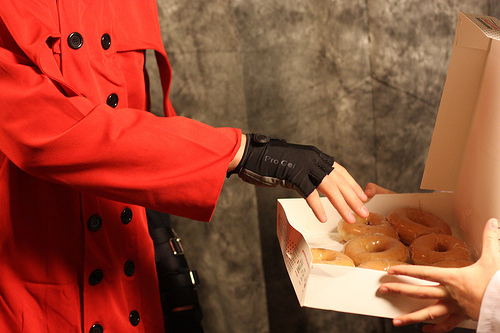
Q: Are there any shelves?
A: No, there are no shelves.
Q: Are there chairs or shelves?
A: No, there are no shelves or chairs.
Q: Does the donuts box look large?
A: Yes, the box is large.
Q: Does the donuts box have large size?
A: Yes, the box is large.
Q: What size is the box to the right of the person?
A: The box is large.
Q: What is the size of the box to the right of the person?
A: The box is large.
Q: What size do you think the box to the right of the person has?
A: The box has large size.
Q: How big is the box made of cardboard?
A: The box is large.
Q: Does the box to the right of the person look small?
A: No, the box is large.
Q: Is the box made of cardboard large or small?
A: The box is large.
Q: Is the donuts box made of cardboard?
A: Yes, the box is made of cardboard.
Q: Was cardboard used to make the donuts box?
A: Yes, the box is made of cardboard.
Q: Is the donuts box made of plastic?
A: No, the box is made of cardboard.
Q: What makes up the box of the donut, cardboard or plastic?
A: The box is made of cardboard.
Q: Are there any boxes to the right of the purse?
A: Yes, there is a box to the right of the purse.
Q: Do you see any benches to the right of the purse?
A: No, there is a box to the right of the purse.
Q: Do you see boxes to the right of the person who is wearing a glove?
A: Yes, there is a box to the right of the person.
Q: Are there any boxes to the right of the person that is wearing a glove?
A: Yes, there is a box to the right of the person.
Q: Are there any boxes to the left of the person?
A: No, the box is to the right of the person.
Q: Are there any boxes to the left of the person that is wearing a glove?
A: No, the box is to the right of the person.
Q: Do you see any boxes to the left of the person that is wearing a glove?
A: No, the box is to the right of the person.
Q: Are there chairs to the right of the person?
A: No, there is a box to the right of the person.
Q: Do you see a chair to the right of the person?
A: No, there is a box to the right of the person.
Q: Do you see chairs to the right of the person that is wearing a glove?
A: No, there is a box to the right of the person.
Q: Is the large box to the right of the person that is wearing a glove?
A: Yes, the box is to the right of the person.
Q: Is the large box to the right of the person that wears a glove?
A: Yes, the box is to the right of the person.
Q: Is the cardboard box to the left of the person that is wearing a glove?
A: No, the box is to the right of the person.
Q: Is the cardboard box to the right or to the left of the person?
A: The box is to the right of the person.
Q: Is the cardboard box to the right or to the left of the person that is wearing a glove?
A: The box is to the right of the person.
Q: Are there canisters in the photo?
A: No, there are no canisters.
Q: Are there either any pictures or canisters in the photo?
A: No, there are no canisters or pictures.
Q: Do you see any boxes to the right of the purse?
A: Yes, there is a box to the right of the purse.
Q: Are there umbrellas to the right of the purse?
A: No, there is a box to the right of the purse.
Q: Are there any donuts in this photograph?
A: Yes, there is a donut.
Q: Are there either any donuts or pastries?
A: Yes, there is a donut.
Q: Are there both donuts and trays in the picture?
A: No, there is a donut but no trays.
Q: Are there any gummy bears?
A: No, there are no gummy bears.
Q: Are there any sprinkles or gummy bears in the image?
A: No, there are no gummy bears or sprinkles.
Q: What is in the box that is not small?
A: The doughnut is in the box.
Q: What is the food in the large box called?
A: The food is a donut.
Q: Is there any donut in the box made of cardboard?
A: Yes, there is a donut in the box.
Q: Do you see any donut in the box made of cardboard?
A: Yes, there is a donut in the box.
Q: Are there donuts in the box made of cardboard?
A: Yes, there is a donut in the box.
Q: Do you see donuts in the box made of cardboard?
A: Yes, there is a donut in the box.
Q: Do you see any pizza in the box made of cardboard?
A: No, there is a donut in the box.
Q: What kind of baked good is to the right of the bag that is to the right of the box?
A: The food is a donut.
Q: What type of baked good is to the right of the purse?
A: The food is a donut.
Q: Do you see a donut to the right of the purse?
A: Yes, there is a donut to the right of the purse.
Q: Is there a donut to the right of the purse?
A: Yes, there is a donut to the right of the purse.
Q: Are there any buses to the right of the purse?
A: No, there is a donut to the right of the purse.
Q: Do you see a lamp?
A: No, there are no lamps.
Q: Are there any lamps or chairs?
A: No, there are no lamps or chairs.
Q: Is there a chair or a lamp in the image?
A: No, there are no lamps or chairs.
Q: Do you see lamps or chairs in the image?
A: No, there are no lamps or chairs.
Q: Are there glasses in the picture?
A: No, there are no glasses.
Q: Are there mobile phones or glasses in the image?
A: No, there are no glasses or mobile phones.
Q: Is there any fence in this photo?
A: No, there are no fences.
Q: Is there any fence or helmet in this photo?
A: No, there are no fences or helmets.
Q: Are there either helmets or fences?
A: No, there are no fences or helmets.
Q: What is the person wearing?
A: The person is wearing a glove.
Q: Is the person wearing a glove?
A: Yes, the person is wearing a glove.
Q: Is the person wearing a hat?
A: No, the person is wearing a glove.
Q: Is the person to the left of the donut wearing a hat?
A: No, the person is wearing a glove.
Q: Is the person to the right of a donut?
A: No, the person is to the left of a donut.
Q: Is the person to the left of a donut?
A: Yes, the person is to the left of a donut.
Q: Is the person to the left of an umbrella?
A: No, the person is to the left of a donut.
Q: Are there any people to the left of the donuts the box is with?
A: Yes, there is a person to the left of the donuts.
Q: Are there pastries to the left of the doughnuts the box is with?
A: No, there is a person to the left of the donuts.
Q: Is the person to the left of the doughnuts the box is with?
A: Yes, the person is to the left of the doughnuts.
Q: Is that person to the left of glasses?
A: No, the person is to the left of the doughnuts.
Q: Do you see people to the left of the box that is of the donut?
A: Yes, there is a person to the left of the box.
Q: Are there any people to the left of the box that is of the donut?
A: Yes, there is a person to the left of the box.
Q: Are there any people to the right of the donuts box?
A: No, the person is to the left of the box.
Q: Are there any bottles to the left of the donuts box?
A: No, there is a person to the left of the box.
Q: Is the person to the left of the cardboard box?
A: Yes, the person is to the left of the box.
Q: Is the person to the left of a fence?
A: No, the person is to the left of the box.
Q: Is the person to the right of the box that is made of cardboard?
A: No, the person is to the left of the box.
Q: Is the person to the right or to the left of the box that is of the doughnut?
A: The person is to the left of the box.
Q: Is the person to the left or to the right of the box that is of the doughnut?
A: The person is to the left of the box.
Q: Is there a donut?
A: Yes, there are donuts.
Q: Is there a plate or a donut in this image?
A: Yes, there are donuts.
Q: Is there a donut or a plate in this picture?
A: Yes, there are donuts.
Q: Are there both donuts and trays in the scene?
A: No, there are donuts but no trays.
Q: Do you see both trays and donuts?
A: No, there are donuts but no trays.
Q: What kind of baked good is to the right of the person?
A: The food is donuts.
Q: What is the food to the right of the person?
A: The food is donuts.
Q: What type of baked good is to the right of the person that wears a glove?
A: The food is donuts.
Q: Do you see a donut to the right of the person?
A: Yes, there are donuts to the right of the person.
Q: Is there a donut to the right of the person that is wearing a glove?
A: Yes, there are donuts to the right of the person.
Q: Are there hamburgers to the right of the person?
A: No, there are donuts to the right of the person.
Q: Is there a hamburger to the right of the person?
A: No, there are donuts to the right of the person.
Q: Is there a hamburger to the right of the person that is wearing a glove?
A: No, there are donuts to the right of the person.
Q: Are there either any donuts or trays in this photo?
A: Yes, there are donuts.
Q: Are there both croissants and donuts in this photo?
A: No, there are donuts but no croissants.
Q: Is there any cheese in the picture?
A: No, there is no cheese.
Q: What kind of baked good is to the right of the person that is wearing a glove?
A: The food is donuts.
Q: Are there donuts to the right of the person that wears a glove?
A: Yes, there are donuts to the right of the person.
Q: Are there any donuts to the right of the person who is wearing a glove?
A: Yes, there are donuts to the right of the person.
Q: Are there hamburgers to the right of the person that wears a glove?
A: No, there are donuts to the right of the person.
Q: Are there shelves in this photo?
A: No, there are no shelves.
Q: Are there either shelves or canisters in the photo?
A: No, there are no shelves or canisters.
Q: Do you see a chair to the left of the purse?
A: No, there is a box to the left of the purse.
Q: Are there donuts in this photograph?
A: Yes, there is a donut.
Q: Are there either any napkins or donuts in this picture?
A: Yes, there is a donut.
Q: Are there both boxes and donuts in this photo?
A: Yes, there are both a donut and a box.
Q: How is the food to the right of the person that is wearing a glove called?
A: The food is a donut.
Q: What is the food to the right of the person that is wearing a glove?
A: The food is a donut.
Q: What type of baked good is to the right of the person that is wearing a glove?
A: The food is a donut.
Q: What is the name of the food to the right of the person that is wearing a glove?
A: The food is a donut.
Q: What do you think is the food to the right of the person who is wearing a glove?
A: The food is a donut.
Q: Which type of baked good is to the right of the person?
A: The food is a donut.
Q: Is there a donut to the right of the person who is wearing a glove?
A: Yes, there is a donut to the right of the person.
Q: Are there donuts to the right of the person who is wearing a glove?
A: Yes, there is a donut to the right of the person.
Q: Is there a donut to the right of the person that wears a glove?
A: Yes, there is a donut to the right of the person.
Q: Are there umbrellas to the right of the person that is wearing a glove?
A: No, there is a donut to the right of the person.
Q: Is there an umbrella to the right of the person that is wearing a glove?
A: No, there is a donut to the right of the person.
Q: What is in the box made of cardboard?
A: The doughnut is in the box.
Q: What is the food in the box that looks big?
A: The food is a donut.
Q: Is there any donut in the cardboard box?
A: Yes, there is a donut in the box.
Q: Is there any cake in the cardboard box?
A: No, there is a donut in the box.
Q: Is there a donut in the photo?
A: Yes, there is a donut.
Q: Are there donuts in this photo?
A: Yes, there is a donut.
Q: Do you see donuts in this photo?
A: Yes, there is a donut.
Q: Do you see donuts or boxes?
A: Yes, there is a donut.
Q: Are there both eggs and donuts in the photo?
A: No, there is a donut but no eggs.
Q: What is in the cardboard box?
A: The doughnut is in the box.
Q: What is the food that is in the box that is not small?
A: The food is a donut.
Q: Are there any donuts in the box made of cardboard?
A: Yes, there is a donut in the box.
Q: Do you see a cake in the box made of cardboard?
A: No, there is a donut in the box.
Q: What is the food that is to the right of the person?
A: The food is a donut.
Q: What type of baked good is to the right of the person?
A: The food is a donut.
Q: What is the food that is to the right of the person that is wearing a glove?
A: The food is a donut.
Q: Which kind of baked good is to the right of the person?
A: The food is a donut.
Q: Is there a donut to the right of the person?
A: Yes, there is a donut to the right of the person.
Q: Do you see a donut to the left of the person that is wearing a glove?
A: No, the donut is to the right of the person.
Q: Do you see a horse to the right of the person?
A: No, there is a donut to the right of the person.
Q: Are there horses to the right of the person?
A: No, there is a donut to the right of the person.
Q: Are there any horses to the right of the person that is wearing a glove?
A: No, there is a donut to the right of the person.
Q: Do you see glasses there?
A: No, there are no glasses.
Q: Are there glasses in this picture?
A: No, there are no glasses.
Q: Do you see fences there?
A: No, there are no fences.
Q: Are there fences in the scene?
A: No, there are no fences.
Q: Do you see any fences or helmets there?
A: No, there are no fences or helmets.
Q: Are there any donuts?
A: Yes, there is a donut.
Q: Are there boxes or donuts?
A: Yes, there is a donut.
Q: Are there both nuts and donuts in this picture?
A: No, there is a donut but no nuts.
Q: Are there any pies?
A: No, there are no pies.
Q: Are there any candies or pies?
A: No, there are no pies or candies.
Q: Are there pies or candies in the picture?
A: No, there are no pies or candies.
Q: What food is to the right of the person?
A: The food is a donut.